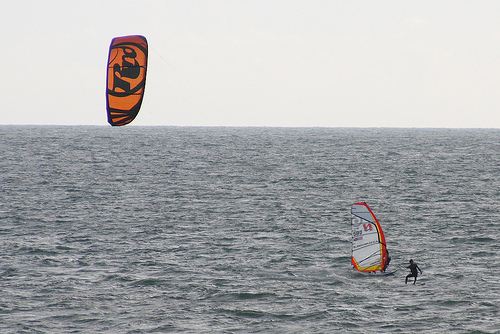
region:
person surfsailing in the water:
[402, 257, 421, 284]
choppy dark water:
[131, 247, 185, 272]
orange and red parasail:
[103, 31, 148, 128]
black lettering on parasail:
[110, 45, 139, 95]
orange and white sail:
[347, 200, 389, 271]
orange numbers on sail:
[361, 222, 371, 231]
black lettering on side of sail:
[349, 230, 366, 242]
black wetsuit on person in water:
[402, 262, 420, 285]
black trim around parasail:
[105, 32, 149, 127]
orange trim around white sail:
[348, 196, 388, 272]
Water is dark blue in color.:
[85, 193, 299, 309]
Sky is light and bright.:
[204, 39, 371, 120]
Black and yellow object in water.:
[77, 41, 179, 131]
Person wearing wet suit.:
[395, 257, 441, 303]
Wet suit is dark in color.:
[401, 244, 433, 326]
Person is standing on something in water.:
[399, 275, 429, 288]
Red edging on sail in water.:
[353, 190, 390, 228]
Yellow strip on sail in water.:
[350, 248, 385, 273]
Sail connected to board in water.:
[347, 245, 408, 295]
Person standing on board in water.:
[379, 246, 394, 272]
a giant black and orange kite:
[103, 34, 150, 130]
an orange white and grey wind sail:
[350, 199, 391, 274]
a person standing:
[404, 256, 422, 281]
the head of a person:
[408, 257, 416, 269]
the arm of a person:
[415, 262, 422, 271]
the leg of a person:
[401, 271, 411, 283]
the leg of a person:
[411, 273, 418, 283]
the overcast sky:
[2, 1, 498, 126]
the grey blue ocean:
[1, 125, 498, 330]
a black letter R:
[110, 63, 141, 90]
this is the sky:
[235, 7, 486, 92]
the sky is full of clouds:
[273, 29, 434, 91]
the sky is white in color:
[241, 11, 441, 98]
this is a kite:
[96, 32, 149, 128]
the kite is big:
[101, 32, 154, 124]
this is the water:
[191, 139, 296, 186]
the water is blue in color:
[156, 180, 265, 260]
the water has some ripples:
[226, 195, 310, 332]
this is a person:
[402, 250, 422, 284]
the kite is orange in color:
[113, 97, 130, 104]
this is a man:
[403, 257, 427, 288]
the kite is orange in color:
[98, 32, 152, 127]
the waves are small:
[106, 151, 264, 331]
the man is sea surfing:
[342, 197, 429, 308]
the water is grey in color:
[128, 170, 283, 328]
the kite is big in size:
[94, 30, 152, 130]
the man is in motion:
[404, 255, 424, 282]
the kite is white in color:
[357, 222, 376, 249]